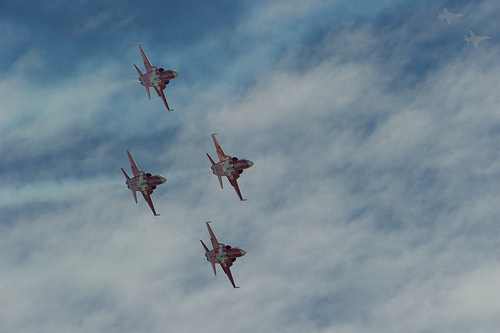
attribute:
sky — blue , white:
[0, 0, 499, 332]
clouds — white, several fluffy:
[0, 0, 499, 331]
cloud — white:
[358, 105, 434, 224]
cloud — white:
[204, 61, 376, 140]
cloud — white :
[0, 0, 499, 332]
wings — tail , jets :
[211, 130, 246, 206]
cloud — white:
[196, 61, 384, 151]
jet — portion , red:
[199, 129, 258, 207]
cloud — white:
[275, 64, 484, 191]